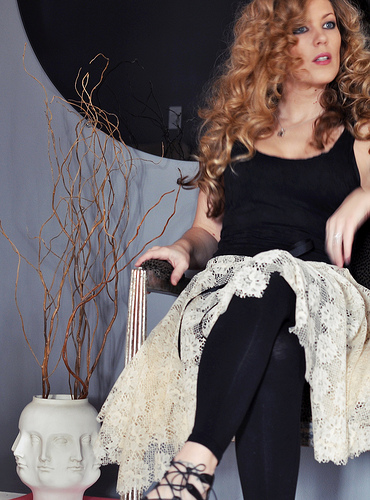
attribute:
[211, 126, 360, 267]
shirt — black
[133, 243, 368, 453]
skirt — white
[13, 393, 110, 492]
container — white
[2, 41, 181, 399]
sticks — brown, curly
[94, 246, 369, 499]
shawl — lacy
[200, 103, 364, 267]
tank top — black 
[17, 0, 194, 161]
mirror — large, round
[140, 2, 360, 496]
top — black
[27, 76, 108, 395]
curely sticks — curly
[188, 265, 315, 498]
tights — black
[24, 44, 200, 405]
branches — dried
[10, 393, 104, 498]
planter — white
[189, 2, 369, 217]
curly hair — long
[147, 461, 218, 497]
shoes — black 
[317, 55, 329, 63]
teeth — white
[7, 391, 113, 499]
vase — white 